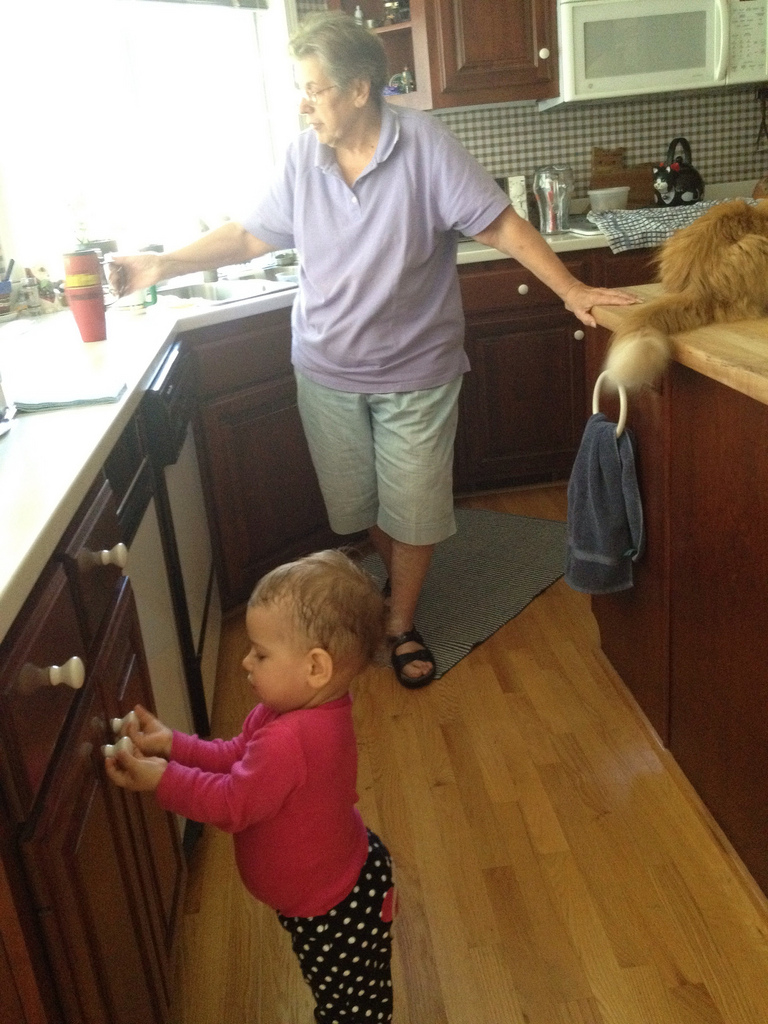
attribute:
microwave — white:
[549, 3, 764, 110]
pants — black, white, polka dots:
[280, 827, 394, 1021]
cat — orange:
[600, 197, 763, 405]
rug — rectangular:
[572, 421, 648, 581]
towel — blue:
[530, 381, 731, 582]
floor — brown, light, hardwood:
[176, 469, 767, 1021]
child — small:
[125, 538, 416, 1016]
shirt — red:
[195, 697, 370, 885]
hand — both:
[94, 734, 173, 799]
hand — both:
[112, 703, 180, 761]